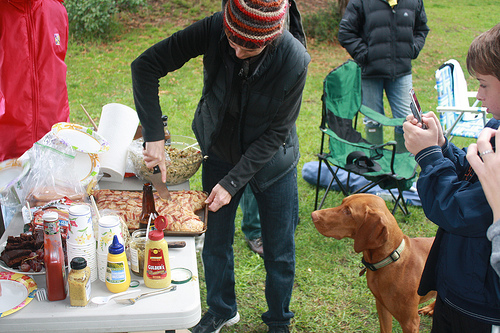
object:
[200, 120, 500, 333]
ground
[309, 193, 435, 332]
dog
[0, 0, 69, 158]
person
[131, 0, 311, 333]
person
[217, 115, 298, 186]
wall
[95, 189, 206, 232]
pizza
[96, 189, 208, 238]
metal tray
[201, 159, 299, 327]
denim pants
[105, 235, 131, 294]
mustard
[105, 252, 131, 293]
yellow mustard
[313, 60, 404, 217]
chair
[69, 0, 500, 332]
grass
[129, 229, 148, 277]
jar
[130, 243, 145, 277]
pickles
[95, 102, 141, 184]
paper towels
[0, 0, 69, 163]
red jacket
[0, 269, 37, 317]
paper plate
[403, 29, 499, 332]
boy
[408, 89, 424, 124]
cell phone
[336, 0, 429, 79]
winter jacket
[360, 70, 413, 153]
pants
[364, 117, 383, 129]
knee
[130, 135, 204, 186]
glass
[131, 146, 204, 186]
pasta salad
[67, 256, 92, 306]
mustard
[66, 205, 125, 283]
paper cups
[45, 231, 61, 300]
ketchup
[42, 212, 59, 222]
lid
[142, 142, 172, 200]
knife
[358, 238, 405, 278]
collar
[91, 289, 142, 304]
plastic spoon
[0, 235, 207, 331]
table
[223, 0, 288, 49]
beanie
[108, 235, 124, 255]
lid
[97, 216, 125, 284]
cup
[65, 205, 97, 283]
cup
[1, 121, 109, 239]
pile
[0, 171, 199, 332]
plate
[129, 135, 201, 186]
bowl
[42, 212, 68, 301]
bottle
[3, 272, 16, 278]
rim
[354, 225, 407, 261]
neck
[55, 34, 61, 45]
white logo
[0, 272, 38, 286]
border